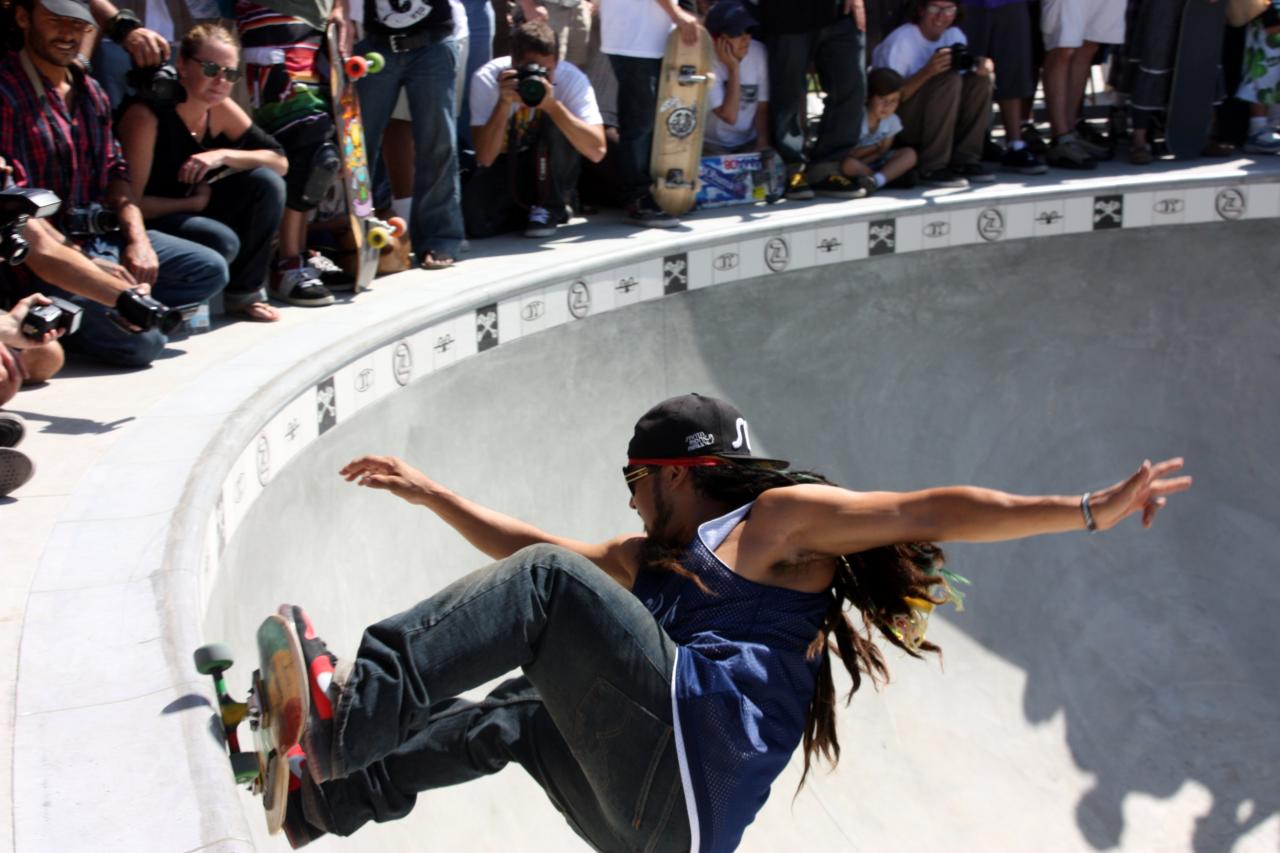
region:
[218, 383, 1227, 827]
man is on a skateboard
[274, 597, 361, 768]
red and black shoe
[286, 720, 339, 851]
red and black shoe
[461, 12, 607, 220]
man is taking a picture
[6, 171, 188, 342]
person is holding a camera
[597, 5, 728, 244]
person is holding a skateboard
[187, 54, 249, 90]
woman has black sunglasses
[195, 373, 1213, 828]
a skater on his board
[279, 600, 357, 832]
red, black, and white skating shoes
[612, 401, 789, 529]
a man wearing a backwards ball cap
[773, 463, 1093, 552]
a person's outstretched arm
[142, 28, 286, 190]
a woman wearing a black shirt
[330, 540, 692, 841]
a person wearing blue jeans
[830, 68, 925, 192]
a child sitting cross legged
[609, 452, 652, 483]
man wearing black glasses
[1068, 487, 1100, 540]
man with a band on his wrist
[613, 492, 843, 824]
man wearing a shirt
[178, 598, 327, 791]
skateboard on the wall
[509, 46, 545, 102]
person taking a picture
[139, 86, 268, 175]
woman wearing a black shirt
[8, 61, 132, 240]
man wearing a purple and black shirt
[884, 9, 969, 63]
man wearing a white tee shirt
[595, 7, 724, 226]
person holding wood skateboard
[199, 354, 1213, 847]
man in black hat riding skateboard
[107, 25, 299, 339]
woman in black sunglasses sitting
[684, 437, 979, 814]
skater has long hair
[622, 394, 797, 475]
skater is wearing his hat backwards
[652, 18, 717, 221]
person is holding a skateboard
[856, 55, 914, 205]
child is sitting on the edge of ramp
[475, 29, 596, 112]
man is taking a picture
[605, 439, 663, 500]
skater is wearing sunglasses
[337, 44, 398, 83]
red and green wheels on the skateboard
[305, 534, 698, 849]
skater is wearing jeans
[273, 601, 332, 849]
skater's shoes are red and black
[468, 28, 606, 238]
person taking a photo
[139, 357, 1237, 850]
the person is skating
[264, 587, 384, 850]
red on the shoes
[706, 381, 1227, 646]
the arm is extended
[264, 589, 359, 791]
part of a human body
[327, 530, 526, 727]
part of a human body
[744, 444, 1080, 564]
part of a human body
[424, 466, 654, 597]
part of a human body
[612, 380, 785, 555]
part of a human body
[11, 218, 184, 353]
part of a human body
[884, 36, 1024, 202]
A person at a skate park.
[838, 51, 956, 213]
A person at a skate park.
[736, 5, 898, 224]
A person at a skate park.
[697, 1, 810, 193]
A person at a skate park.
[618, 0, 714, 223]
A person at a skate park.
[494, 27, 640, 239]
A person at a skate park.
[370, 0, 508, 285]
A person at a skate park.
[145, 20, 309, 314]
A person at a skate park.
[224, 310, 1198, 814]
A person at a skate park.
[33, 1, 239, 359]
A person at a skate park.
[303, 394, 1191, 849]
a man on a skateboard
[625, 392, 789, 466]
a cap on a man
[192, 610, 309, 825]
a skateboard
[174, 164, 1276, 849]
a skateboard ramp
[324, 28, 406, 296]
a skateboard in a man's hand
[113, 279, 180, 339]
a camera